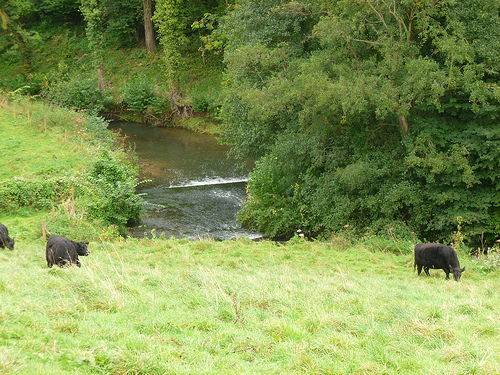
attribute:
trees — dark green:
[221, 0, 497, 253]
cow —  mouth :
[41, 233, 93, 275]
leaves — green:
[275, 123, 413, 213]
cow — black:
[0, 223, 18, 255]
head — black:
[445, 262, 465, 282]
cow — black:
[37, 225, 94, 270]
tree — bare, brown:
[136, 2, 154, 53]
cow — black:
[405, 238, 495, 298]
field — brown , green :
[1, 232, 487, 373]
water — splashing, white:
[167, 163, 239, 195]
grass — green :
[7, 234, 494, 369]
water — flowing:
[128, 112, 260, 247]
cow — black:
[405, 234, 467, 279]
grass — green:
[155, 288, 242, 351]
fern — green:
[98, 173, 143, 223]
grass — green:
[138, 268, 282, 321]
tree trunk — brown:
[133, 28, 162, 61]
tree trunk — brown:
[87, 63, 120, 101]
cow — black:
[402, 225, 469, 282]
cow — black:
[412, 243, 464, 280]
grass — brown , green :
[2, 92, 499, 370]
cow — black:
[405, 235, 467, 285]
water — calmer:
[113, 119, 259, 239]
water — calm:
[138, 119, 273, 243]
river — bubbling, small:
[91, 119, 253, 235]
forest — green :
[271, 50, 448, 143]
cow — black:
[412, 243, 464, 286]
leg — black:
[415, 266, 422, 276]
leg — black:
[422, 266, 429, 278]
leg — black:
[443, 269, 450, 280]